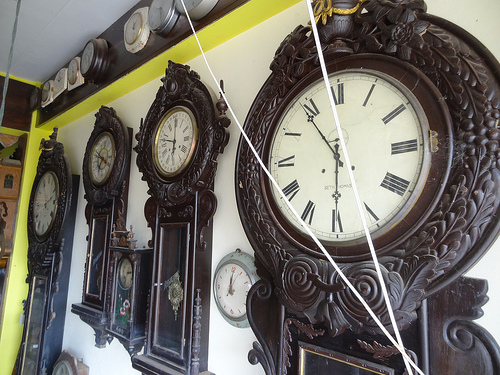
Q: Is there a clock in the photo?
A: Yes, there is a clock.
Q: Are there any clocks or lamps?
A: Yes, there is a clock.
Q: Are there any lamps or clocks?
A: Yes, there is a clock.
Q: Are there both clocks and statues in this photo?
A: No, there is a clock but no statues.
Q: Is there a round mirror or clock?
A: Yes, there is a round clock.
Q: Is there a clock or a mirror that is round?
A: Yes, the clock is round.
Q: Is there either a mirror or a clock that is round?
A: Yes, the clock is round.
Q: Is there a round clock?
A: Yes, there is a round clock.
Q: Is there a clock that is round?
A: Yes, there is a clock that is round.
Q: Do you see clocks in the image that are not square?
A: Yes, there is a round clock.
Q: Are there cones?
A: No, there are no cones.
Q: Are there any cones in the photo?
A: No, there are no cones.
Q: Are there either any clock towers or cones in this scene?
A: No, there are no cones or clock towers.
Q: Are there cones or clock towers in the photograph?
A: No, there are no cones or clock towers.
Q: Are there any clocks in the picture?
A: Yes, there is a clock.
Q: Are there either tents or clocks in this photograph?
A: Yes, there is a clock.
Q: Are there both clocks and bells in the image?
A: No, there is a clock but no bells.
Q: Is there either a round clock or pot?
A: Yes, there is a round clock.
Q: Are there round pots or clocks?
A: Yes, there is a round clock.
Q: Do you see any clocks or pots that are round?
A: Yes, the clock is round.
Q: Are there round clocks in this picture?
A: Yes, there is a round clock.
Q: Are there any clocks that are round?
A: Yes, there is a clock that is round.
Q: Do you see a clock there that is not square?
A: Yes, there is a round clock.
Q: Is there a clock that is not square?
A: Yes, there is a round clock.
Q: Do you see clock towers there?
A: No, there are no clock towers.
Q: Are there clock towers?
A: No, there are no clock towers.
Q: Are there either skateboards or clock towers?
A: No, there are no clock towers or skateboards.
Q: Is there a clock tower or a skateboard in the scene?
A: No, there are no clock towers or skateboards.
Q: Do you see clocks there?
A: Yes, there is a clock.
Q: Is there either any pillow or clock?
A: Yes, there is a clock.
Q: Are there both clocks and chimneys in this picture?
A: No, there is a clock but no chimneys.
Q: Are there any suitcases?
A: No, there are no suitcases.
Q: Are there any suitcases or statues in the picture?
A: No, there are no suitcases or statues.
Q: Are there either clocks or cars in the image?
A: Yes, there is a clock.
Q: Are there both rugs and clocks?
A: No, there is a clock but no rugs.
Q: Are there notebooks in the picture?
A: No, there are no notebooks.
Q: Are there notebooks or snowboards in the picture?
A: No, there are no notebooks or snowboards.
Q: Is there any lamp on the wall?
A: No, there is a clock on the wall.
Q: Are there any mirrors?
A: No, there are no mirrors.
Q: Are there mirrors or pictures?
A: No, there are no mirrors or pictures.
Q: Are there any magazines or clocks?
A: Yes, there is a clock.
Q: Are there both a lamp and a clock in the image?
A: No, there is a clock but no lamps.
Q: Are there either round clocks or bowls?
A: Yes, there is a round clock.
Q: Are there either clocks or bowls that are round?
A: Yes, the clock is round.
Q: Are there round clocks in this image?
A: Yes, there is a round clock.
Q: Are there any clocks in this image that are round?
A: Yes, there is a clock that is round.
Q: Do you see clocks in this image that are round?
A: Yes, there is a clock that is round.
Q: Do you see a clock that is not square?
A: Yes, there is a round clock.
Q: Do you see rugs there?
A: No, there are no rugs.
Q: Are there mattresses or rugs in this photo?
A: No, there are no rugs or mattresses.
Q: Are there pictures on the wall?
A: No, there is a clock on the wall.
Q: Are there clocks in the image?
A: Yes, there is a clock.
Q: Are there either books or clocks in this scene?
A: Yes, there is a clock.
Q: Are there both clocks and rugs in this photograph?
A: No, there is a clock but no rugs.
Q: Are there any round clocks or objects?
A: Yes, there is a round clock.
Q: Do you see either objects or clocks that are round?
A: Yes, the clock is round.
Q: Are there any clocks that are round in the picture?
A: Yes, there is a round clock.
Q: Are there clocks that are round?
A: Yes, there is a clock that is round.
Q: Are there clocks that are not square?
A: Yes, there is a round clock.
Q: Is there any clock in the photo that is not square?
A: Yes, there is a round clock.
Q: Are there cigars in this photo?
A: No, there are no cigars.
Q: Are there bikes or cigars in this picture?
A: No, there are no cigars or bikes.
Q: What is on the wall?
A: The clock is on the wall.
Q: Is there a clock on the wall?
A: Yes, there is a clock on the wall.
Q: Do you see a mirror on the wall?
A: No, there is a clock on the wall.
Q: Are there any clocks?
A: Yes, there is a clock.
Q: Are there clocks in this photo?
A: Yes, there is a clock.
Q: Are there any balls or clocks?
A: Yes, there is a clock.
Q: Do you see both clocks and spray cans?
A: No, there is a clock but no spray cans.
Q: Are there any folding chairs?
A: No, there are no folding chairs.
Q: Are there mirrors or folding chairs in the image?
A: No, there are no folding chairs or mirrors.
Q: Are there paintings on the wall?
A: No, there is a clock on the wall.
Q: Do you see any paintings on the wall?
A: No, there is a clock on the wall.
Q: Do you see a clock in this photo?
A: Yes, there is a clock.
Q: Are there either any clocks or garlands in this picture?
A: Yes, there is a clock.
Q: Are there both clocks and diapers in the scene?
A: No, there is a clock but no diapers.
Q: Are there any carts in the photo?
A: No, there are no carts.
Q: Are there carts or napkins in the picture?
A: No, there are no carts or napkins.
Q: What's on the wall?
A: The clock is on the wall.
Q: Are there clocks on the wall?
A: Yes, there is a clock on the wall.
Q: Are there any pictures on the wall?
A: No, there is a clock on the wall.